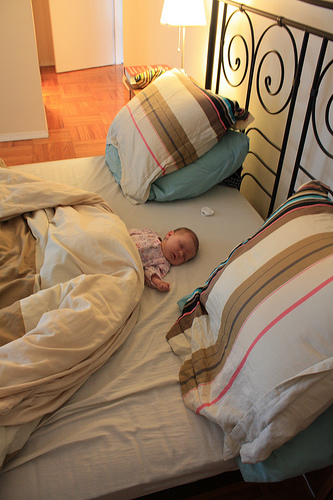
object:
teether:
[202, 206, 216, 216]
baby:
[129, 228, 200, 294]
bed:
[2, 0, 332, 477]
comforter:
[1, 167, 145, 466]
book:
[118, 62, 171, 87]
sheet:
[6, 161, 275, 477]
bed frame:
[200, 0, 332, 219]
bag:
[133, 68, 167, 86]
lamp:
[159, 0, 209, 71]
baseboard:
[1, 127, 47, 147]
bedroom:
[0, 1, 331, 499]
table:
[120, 63, 181, 105]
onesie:
[125, 226, 170, 281]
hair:
[173, 224, 199, 256]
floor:
[0, 66, 141, 166]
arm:
[149, 270, 170, 294]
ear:
[163, 228, 173, 242]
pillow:
[104, 64, 254, 202]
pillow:
[103, 135, 249, 206]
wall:
[1, 1, 53, 144]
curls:
[217, 6, 304, 114]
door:
[48, 1, 118, 72]